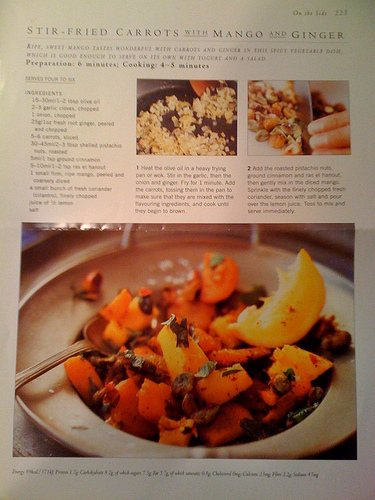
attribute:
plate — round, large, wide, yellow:
[16, 231, 354, 458]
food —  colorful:
[156, 318, 211, 382]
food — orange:
[63, 354, 103, 401]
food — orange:
[97, 287, 132, 325]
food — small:
[156, 417, 192, 444]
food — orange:
[200, 253, 239, 304]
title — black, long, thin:
[35, 15, 368, 45]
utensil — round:
[16, 331, 90, 391]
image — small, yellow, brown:
[244, 75, 351, 157]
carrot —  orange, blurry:
[205, 257, 239, 307]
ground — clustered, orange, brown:
[289, 134, 303, 153]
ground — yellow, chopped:
[220, 130, 238, 157]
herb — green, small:
[196, 357, 220, 380]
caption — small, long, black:
[6, 466, 328, 482]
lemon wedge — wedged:
[231, 246, 326, 349]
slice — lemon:
[230, 243, 324, 345]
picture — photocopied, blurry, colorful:
[121, 64, 242, 171]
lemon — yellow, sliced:
[236, 246, 326, 349]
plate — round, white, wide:
[42, 229, 234, 258]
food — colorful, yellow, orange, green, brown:
[136, 378, 173, 428]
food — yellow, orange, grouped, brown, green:
[74, 274, 338, 432]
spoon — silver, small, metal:
[13, 312, 114, 397]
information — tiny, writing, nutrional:
[12, 466, 321, 479]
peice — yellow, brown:
[153, 318, 208, 384]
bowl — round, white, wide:
[16, 238, 355, 457]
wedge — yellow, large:
[226, 245, 324, 350]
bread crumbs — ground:
[135, 79, 237, 155]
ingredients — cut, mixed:
[62, 248, 353, 445]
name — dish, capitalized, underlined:
[26, 25, 345, 39]